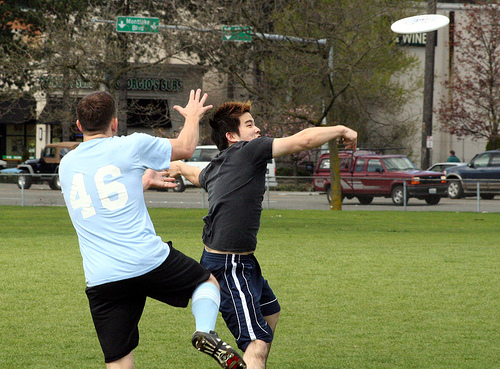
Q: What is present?
A: Cars.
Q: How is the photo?
A: Clear.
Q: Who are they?
A: People.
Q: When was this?
A: Daytime.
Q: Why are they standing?
A: To play.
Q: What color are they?
A: White.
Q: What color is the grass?
A: Green.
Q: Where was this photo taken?
A: In a field.